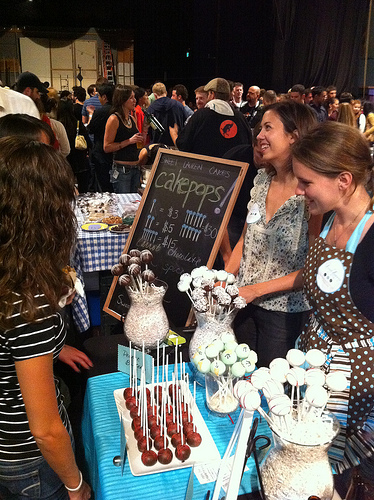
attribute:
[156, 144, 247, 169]
trim — brown, wood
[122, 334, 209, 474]
cakes — round, velvet, red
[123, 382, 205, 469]
cakes — red, round, velvet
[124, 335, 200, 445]
sticks — white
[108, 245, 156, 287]
cakepops — chocolate, round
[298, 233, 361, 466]
apron — brown, blue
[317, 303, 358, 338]
dots — polka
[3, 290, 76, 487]
shirt — black, white, striped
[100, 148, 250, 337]
frame — wood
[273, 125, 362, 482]
woman — brown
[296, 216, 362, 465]
apron — blue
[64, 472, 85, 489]
bracelet — white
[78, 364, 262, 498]
tablecloth — blue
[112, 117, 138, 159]
tanktop — black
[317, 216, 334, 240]
strap — blue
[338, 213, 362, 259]
strap — blue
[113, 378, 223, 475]
tray — white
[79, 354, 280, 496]
tablecloth — blue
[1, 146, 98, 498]
shirt — striped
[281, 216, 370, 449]
apron — brown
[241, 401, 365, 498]
vase — a glass vase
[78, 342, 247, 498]
table cloth — blue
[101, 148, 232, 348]
sign — a chalk board sign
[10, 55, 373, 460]
people — socializing